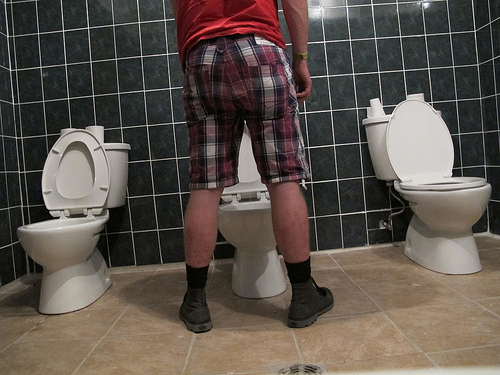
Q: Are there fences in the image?
A: No, there are no fences.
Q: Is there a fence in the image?
A: No, there are no fences.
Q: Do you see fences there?
A: No, there are no fences.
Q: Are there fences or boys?
A: No, there are no fences or boys.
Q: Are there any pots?
A: No, there are no pots.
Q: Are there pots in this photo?
A: No, there are no pots.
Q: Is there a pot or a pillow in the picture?
A: No, there are no pots or pillows.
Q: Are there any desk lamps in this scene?
A: No, there are no desk lamps.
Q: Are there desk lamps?
A: No, there are no desk lamps.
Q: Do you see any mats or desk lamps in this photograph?
A: No, there are no desk lamps or mats.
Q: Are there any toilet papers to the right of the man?
A: Yes, there is a toilet paper to the right of the man.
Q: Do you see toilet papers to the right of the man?
A: Yes, there is a toilet paper to the right of the man.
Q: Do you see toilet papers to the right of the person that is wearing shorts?
A: Yes, there is a toilet paper to the right of the man.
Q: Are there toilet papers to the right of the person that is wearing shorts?
A: Yes, there is a toilet paper to the right of the man.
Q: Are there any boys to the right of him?
A: No, there is a toilet paper to the right of the man.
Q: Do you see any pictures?
A: No, there are no pictures.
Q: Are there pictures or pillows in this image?
A: No, there are no pictures or pillows.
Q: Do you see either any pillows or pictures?
A: No, there are no pictures or pillows.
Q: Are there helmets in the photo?
A: No, there are no helmets.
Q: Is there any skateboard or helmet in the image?
A: No, there are no helmets or skateboards.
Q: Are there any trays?
A: No, there are no trays.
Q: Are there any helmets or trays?
A: No, there are no trays or helmets.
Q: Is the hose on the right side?
A: Yes, the hose is on the right of the image.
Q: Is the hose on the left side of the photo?
A: No, the hose is on the right of the image.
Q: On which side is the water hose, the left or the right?
A: The water hose is on the right of the image.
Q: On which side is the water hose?
A: The water hose is on the right of the image.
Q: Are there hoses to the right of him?
A: Yes, there is a hose to the right of the man.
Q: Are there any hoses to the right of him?
A: Yes, there is a hose to the right of the man.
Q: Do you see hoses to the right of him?
A: Yes, there is a hose to the right of the man.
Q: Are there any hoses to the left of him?
A: No, the hose is to the right of the man.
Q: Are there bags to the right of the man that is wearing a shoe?
A: No, there is a hose to the right of the man.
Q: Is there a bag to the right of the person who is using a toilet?
A: No, there is a hose to the right of the man.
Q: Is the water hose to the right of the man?
A: Yes, the water hose is to the right of the man.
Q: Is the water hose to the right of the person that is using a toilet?
A: Yes, the water hose is to the right of the man.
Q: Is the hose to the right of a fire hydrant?
A: No, the hose is to the right of the man.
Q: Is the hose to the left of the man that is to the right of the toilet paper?
A: No, the hose is to the right of the man.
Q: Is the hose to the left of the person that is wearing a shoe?
A: No, the hose is to the right of the man.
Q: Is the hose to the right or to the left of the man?
A: The hose is to the right of the man.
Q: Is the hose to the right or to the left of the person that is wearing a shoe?
A: The hose is to the right of the man.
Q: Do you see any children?
A: No, there are no children.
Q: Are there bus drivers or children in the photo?
A: No, there are no children or bus drivers.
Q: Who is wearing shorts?
A: The man is wearing shorts.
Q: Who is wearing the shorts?
A: The man is wearing shorts.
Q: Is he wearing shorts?
A: Yes, the man is wearing shorts.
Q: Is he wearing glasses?
A: No, the man is wearing shorts.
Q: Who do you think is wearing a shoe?
A: The man is wearing a shoe.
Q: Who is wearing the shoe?
A: The man is wearing a shoe.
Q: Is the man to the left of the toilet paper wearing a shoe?
A: Yes, the man is wearing a shoe.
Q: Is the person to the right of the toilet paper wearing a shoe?
A: Yes, the man is wearing a shoe.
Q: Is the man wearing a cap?
A: No, the man is wearing a shoe.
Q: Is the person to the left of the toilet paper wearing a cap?
A: No, the man is wearing a shoe.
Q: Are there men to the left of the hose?
A: Yes, there is a man to the left of the hose.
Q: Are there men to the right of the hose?
A: No, the man is to the left of the hose.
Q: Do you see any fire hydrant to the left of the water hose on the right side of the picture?
A: No, there is a man to the left of the hose.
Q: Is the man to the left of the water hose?
A: Yes, the man is to the left of the water hose.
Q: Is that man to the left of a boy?
A: No, the man is to the left of the water hose.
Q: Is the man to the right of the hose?
A: No, the man is to the left of the hose.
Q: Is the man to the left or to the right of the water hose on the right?
A: The man is to the left of the hose.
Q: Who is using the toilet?
A: The man is using the toilet.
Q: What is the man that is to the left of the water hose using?
A: The man is using a toilet.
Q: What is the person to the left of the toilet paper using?
A: The man is using a toilet.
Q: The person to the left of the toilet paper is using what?
A: The man is using a toilet.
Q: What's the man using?
A: The man is using a toilet.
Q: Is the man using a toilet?
A: Yes, the man is using a toilet.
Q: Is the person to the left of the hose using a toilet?
A: Yes, the man is using a toilet.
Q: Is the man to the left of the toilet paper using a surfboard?
A: No, the man is using a toilet.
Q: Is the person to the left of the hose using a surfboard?
A: No, the man is using a toilet.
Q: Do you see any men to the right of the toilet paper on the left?
A: Yes, there is a man to the right of the toilet paper.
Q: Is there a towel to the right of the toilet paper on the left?
A: No, there is a man to the right of the toilet paper.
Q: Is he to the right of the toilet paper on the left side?
A: Yes, the man is to the right of the toilet paper.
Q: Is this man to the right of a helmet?
A: No, the man is to the right of the toilet paper.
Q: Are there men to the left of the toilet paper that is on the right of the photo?
A: Yes, there is a man to the left of the toilet paper.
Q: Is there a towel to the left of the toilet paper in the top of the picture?
A: No, there is a man to the left of the toilet paper.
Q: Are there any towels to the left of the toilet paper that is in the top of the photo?
A: No, there is a man to the left of the toilet paper.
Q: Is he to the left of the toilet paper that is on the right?
A: Yes, the man is to the left of the toilet paper.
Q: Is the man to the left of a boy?
A: No, the man is to the left of the toilet paper.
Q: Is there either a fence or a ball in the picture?
A: No, there are no fences or balls.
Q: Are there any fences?
A: No, there are no fences.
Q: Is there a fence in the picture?
A: No, there are no fences.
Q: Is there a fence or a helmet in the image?
A: No, there are no fences or helmets.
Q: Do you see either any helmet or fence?
A: No, there are no fences or helmets.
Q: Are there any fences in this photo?
A: No, there are no fences.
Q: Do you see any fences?
A: No, there are no fences.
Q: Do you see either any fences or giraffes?
A: No, there are no fences or giraffes.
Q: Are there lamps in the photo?
A: No, there are no lamps.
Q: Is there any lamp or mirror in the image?
A: No, there are no lamps or mirrors.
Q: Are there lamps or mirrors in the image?
A: No, there are no lamps or mirrors.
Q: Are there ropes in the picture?
A: No, there are no ropes.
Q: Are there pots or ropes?
A: No, there are no ropes or pots.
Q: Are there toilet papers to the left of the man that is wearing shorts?
A: Yes, there is a toilet paper to the left of the man.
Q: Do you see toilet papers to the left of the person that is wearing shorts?
A: Yes, there is a toilet paper to the left of the man.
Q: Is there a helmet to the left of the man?
A: No, there is a toilet paper to the left of the man.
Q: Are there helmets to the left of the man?
A: No, there is a toilet paper to the left of the man.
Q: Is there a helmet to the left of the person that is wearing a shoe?
A: No, there is a toilet paper to the left of the man.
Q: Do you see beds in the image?
A: No, there are no beds.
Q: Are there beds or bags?
A: No, there are no beds or bags.